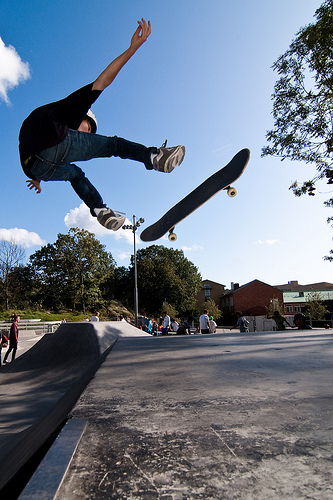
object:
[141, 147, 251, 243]
skateboard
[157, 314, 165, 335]
person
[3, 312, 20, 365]
person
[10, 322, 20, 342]
shirt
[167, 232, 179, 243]
wheel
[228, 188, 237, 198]
wheel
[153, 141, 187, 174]
shoe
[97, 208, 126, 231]
shoe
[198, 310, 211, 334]
person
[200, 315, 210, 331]
shirt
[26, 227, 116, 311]
tree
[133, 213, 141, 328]
pole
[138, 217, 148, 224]
light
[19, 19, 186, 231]
skater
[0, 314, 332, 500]
park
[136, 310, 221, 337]
people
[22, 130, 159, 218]
jeans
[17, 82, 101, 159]
shirt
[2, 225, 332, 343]
background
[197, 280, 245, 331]
house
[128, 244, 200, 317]
tree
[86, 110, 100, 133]
helmet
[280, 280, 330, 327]
building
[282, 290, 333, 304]
roof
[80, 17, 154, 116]
arm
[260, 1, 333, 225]
tree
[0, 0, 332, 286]
sky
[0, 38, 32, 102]
cloud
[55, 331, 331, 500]
concrete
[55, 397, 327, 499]
stain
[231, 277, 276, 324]
building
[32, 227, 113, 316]
leaves